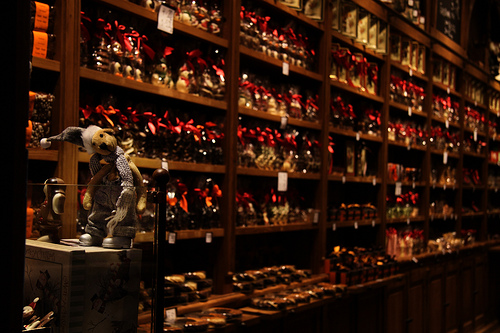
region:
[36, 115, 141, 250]
a stuffed animal standing on a shelf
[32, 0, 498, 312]
shelves filled with assorted items on them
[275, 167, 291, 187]
a piece of paper on the shelf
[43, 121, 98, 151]
the hat the bear is wearing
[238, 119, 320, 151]
assorted price tags on the toys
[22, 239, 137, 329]
a box sitting by the shelves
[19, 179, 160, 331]
some glass next to the box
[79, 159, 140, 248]
a clown costume the bear is wearing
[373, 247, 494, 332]
cabinets under the shelves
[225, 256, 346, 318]
toy cars sitting on a shelf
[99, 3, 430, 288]
dolls are on the shelf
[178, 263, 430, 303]
bottles are on the shelf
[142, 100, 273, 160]
items are adorned with red ribbon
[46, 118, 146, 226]
the kangaroo is wearing a hat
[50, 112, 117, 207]
the kangaroo is brown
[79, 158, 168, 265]
the kangaroo is wearing a scarf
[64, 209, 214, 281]
the doll is wearing a shoe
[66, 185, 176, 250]
the doll is wearing pants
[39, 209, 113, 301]
the doll is on a metal stand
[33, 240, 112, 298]
the metal stand is engraved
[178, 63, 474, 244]
so many things kept for sale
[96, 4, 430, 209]
wooden rack in the shop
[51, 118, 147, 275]
toy kept in the table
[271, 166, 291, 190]
white color price tag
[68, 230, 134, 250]
toy's black color shoes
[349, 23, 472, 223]
many things kept in the rack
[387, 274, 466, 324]
wooden wardrobe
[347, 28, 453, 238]
lot of wooden racks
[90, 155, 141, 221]
teddy bear backbag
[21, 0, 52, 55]
two whitew color price tags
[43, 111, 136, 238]
bear on stand in glass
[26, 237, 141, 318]
stand that bear rests on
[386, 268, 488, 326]
cabinets on the lower level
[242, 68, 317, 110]
candies on shelf in row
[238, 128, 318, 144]
ribbon on containers on shelf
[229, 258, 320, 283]
wrapped goods on the shelf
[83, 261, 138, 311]
design on box bear rests on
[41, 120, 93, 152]
hat on bear on stand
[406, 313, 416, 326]
knob on the cabinet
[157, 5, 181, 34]
paper hanging from shelf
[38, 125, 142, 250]
A dog with a tilted head and shoes.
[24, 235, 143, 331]
A grey wooden box a dog is on.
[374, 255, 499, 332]
Brown cabinets on the bottom of the shelves.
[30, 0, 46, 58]
Two orange visible labels on top of each other.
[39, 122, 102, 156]
A grey and white furry hat.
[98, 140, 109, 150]
A black nose on a dog.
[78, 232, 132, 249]
White shoes on a dog.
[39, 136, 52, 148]
White ball on the end of a hat.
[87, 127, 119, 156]
A brown dog face with a black nose.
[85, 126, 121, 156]
Brown dog face with black nose.